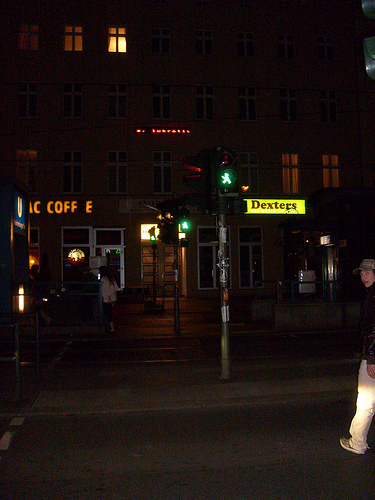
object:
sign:
[245, 197, 306, 215]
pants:
[348, 358, 375, 453]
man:
[339, 257, 374, 454]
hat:
[353, 256, 374, 275]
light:
[219, 171, 231, 186]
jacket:
[99, 275, 119, 303]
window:
[236, 227, 266, 288]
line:
[0, 428, 14, 450]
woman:
[101, 265, 119, 333]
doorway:
[140, 239, 181, 296]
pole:
[216, 205, 232, 381]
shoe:
[338, 437, 368, 455]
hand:
[366, 361, 375, 381]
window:
[94, 244, 125, 290]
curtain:
[281, 152, 301, 195]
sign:
[15, 195, 27, 231]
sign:
[22, 197, 93, 217]